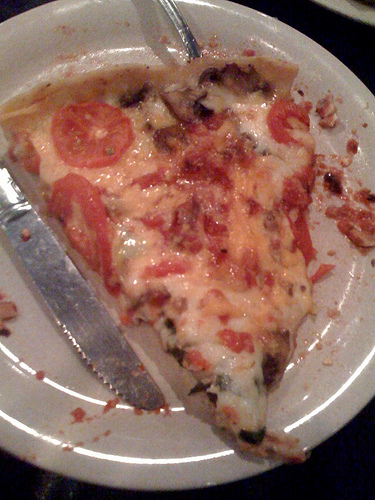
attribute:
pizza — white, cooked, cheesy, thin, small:
[39, 72, 327, 328]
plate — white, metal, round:
[11, 5, 372, 380]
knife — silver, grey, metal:
[24, 197, 136, 409]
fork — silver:
[169, 8, 217, 65]